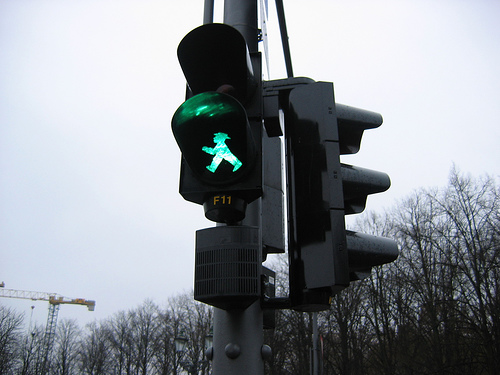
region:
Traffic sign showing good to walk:
[171, 90, 256, 228]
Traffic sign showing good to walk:
[139, 54, 258, 180]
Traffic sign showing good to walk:
[163, 20, 398, 321]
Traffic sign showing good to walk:
[188, 75, 299, 150]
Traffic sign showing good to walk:
[162, 94, 369, 203]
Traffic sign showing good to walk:
[162, 8, 274, 229]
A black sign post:
[170, 55, 375, 312]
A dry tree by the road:
[430, 169, 495, 337]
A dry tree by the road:
[401, 190, 451, 337]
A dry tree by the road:
[158, 294, 185, 370]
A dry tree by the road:
[132, 305, 158, 370]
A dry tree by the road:
[110, 315, 132, 370]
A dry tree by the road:
[79, 319, 116, 371]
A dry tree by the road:
[58, 314, 88, 372]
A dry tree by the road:
[24, 319, 45, 372]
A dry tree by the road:
[2, 306, 24, 373]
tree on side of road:
[406, 211, 448, 356]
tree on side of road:
[334, 290, 359, 363]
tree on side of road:
[149, 315, 166, 368]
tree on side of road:
[102, 323, 127, 370]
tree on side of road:
[70, 324, 97, 371]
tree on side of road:
[441, 190, 483, 363]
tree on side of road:
[393, 221, 434, 363]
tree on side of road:
[371, 300, 386, 357]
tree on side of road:
[343, 301, 358, 354]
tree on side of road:
[261, 312, 293, 366]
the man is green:
[195, 123, 245, 187]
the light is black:
[170, 20, 407, 341]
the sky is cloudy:
[19, 57, 148, 212]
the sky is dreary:
[380, 10, 450, 117]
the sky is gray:
[27, 92, 136, 232]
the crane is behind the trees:
[5, 281, 93, 328]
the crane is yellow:
[7, 275, 107, 323]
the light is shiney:
[289, 84, 340, 290]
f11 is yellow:
[202, 191, 238, 209]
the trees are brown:
[411, 199, 476, 311]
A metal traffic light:
[171, 0, 398, 374]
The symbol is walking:
[202, 131, 242, 173]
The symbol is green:
[202, 131, 241, 171]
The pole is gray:
[207, 0, 271, 374]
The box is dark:
[262, 76, 398, 311]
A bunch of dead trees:
[2, 162, 499, 374]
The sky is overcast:
[0, 1, 499, 374]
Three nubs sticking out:
[205, 344, 272, 358]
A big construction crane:
[0, 282, 97, 374]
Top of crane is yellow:
[0, 281, 85, 303]